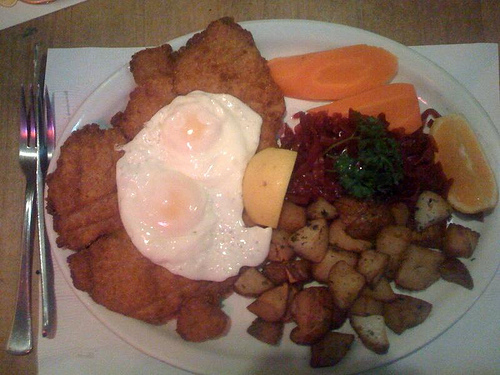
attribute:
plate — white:
[44, 12, 476, 348]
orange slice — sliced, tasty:
[416, 112, 499, 216]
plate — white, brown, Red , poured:
[29, 9, 499, 374]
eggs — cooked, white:
[102, 88, 293, 286]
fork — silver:
[1, 63, 87, 367]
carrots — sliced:
[260, 24, 444, 148]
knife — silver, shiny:
[14, 24, 74, 346]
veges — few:
[11, 8, 325, 363]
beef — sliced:
[44, 193, 237, 346]